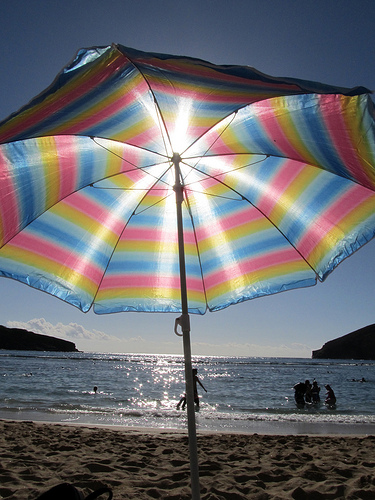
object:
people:
[323, 385, 337, 417]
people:
[311, 381, 324, 409]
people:
[302, 377, 313, 402]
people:
[294, 381, 306, 416]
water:
[0, 353, 372, 429]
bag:
[41, 475, 115, 500]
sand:
[0, 423, 372, 499]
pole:
[173, 158, 198, 500]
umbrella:
[0, 43, 375, 500]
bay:
[0, 345, 373, 498]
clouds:
[6, 318, 157, 352]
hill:
[0, 325, 79, 353]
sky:
[0, 0, 371, 358]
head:
[86, 386, 100, 397]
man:
[187, 364, 206, 411]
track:
[0, 415, 374, 497]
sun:
[79, 90, 329, 300]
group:
[291, 379, 336, 409]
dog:
[173, 395, 200, 414]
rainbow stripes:
[0, 61, 374, 310]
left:
[0, 338, 149, 498]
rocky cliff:
[297, 475, 362, 499]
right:
[292, 242, 374, 496]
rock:
[118, 411, 141, 421]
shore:
[8, 407, 374, 442]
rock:
[244, 411, 275, 432]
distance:
[2, 326, 369, 370]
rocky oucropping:
[306, 322, 375, 360]